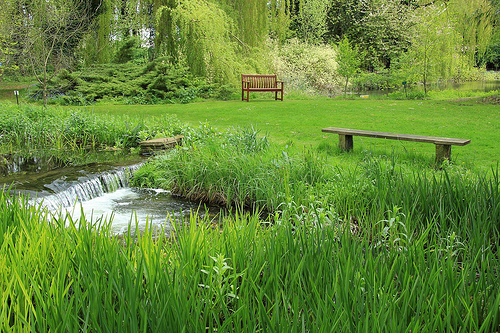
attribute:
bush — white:
[286, 55, 330, 88]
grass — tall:
[276, 204, 419, 319]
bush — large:
[345, 4, 466, 100]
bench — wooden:
[214, 70, 284, 102]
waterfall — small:
[45, 180, 106, 192]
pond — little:
[49, 161, 179, 223]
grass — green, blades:
[267, 208, 461, 331]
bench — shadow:
[239, 65, 289, 105]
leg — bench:
[245, 96, 255, 105]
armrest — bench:
[234, 76, 252, 92]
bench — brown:
[236, 71, 291, 97]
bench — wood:
[219, 63, 290, 106]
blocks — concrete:
[415, 145, 453, 174]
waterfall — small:
[74, 178, 114, 199]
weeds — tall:
[314, 147, 465, 307]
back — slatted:
[240, 78, 278, 90]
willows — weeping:
[175, 11, 224, 79]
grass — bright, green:
[255, 230, 399, 295]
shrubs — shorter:
[26, 61, 207, 111]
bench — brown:
[229, 59, 294, 139]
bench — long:
[299, 105, 474, 185]